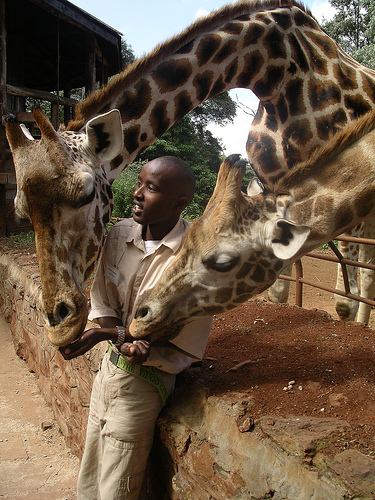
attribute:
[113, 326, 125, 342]
watch — silver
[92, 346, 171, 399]
belt — yellow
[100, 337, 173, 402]
belt — green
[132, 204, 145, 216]
teeth — white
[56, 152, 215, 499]
man — young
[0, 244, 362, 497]
brick wall — half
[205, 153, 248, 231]
horns — big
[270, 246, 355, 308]
fence — wood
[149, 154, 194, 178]
hair — short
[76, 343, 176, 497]
pants — tan, khaki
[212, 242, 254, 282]
eye — gentle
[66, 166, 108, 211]
eye — gentle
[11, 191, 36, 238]
eye — gentle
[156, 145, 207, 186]
hair — black